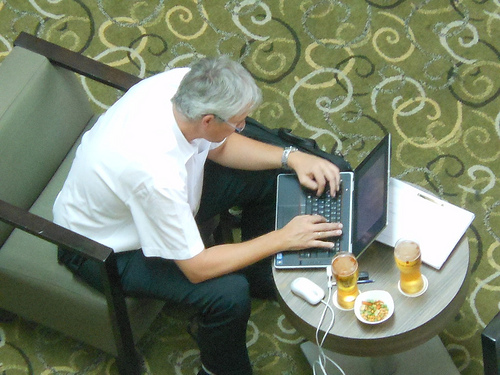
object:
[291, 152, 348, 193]
hand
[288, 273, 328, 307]
mouse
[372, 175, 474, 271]
folder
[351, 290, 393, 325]
bowl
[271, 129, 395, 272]
laptop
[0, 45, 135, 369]
grey chair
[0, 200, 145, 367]
colored arms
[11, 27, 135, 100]
colored arms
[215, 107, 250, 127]
eyeglasses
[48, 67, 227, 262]
white shirt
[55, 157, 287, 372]
jeans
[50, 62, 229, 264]
shirt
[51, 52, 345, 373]
man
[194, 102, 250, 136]
glasses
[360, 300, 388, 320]
food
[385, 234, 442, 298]
beer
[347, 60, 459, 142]
designs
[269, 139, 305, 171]
watch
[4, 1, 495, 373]
design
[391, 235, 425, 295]
glass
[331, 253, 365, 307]
glass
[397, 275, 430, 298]
coaster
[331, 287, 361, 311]
coaster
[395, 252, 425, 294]
drink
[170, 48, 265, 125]
hair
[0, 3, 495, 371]
carpet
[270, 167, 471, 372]
table